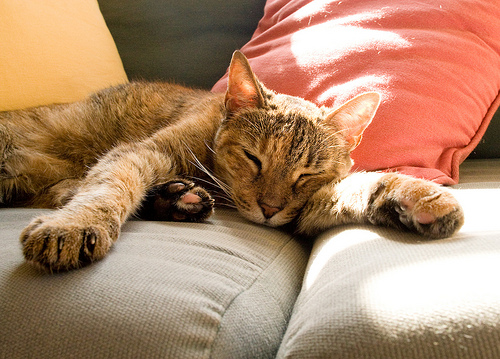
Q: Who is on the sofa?
A: A kitten.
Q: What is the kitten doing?
A: Sleeping.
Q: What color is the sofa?
A: Tan.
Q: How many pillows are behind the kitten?
A: One.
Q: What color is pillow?
A: Peac h.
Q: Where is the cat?
A: On the cushion.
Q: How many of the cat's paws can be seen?
A: Three.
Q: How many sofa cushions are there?
A: Two.